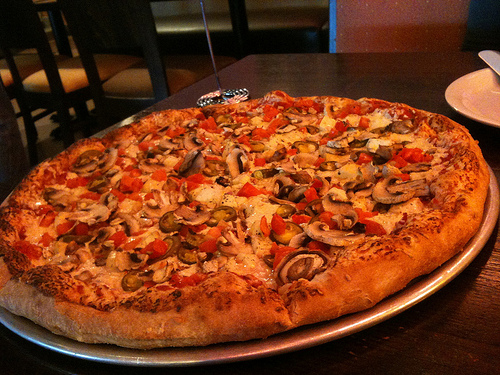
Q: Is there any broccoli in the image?
A: No, there is no broccoli.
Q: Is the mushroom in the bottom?
A: Yes, the mushroom is in the bottom of the image.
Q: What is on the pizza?
A: The mushroom is on the pizza.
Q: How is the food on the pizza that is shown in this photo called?
A: The food is a mushroom.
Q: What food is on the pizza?
A: The food is a mushroom.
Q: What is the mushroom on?
A: The mushroom is on the pizza.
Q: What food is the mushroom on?
A: The mushroom is on the pizza.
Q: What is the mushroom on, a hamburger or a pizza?
A: The mushroom is on a pizza.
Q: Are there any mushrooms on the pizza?
A: Yes, there is a mushroom on the pizza.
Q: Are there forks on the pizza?
A: No, there is a mushroom on the pizza.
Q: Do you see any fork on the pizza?
A: No, there is a mushroom on the pizza.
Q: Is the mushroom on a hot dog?
A: No, the mushroom is on a pizza.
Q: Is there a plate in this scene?
A: Yes, there is a plate.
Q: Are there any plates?
A: Yes, there is a plate.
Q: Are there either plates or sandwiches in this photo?
A: Yes, there is a plate.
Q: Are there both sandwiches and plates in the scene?
A: No, there is a plate but no sandwiches.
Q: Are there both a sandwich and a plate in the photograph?
A: No, there is a plate but no sandwiches.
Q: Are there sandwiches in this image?
A: No, there are no sandwiches.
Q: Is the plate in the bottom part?
A: No, the plate is in the top of the image.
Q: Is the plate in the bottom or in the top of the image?
A: The plate is in the top of the image.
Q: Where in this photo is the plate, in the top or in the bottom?
A: The plate is in the top of the image.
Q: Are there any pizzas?
A: Yes, there is a pizza.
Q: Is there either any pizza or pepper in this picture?
A: Yes, there is a pizza.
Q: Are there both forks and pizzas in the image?
A: No, there is a pizza but no forks.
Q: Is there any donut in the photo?
A: No, there are no donuts.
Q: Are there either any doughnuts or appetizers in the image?
A: No, there are no doughnuts or appetizers.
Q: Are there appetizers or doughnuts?
A: No, there are no doughnuts or appetizers.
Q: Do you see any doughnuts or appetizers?
A: No, there are no doughnuts or appetizers.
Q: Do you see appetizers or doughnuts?
A: No, there are no doughnuts or appetizers.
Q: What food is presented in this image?
A: The food is a pizza.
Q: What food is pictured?
A: The food is a pizza.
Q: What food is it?
A: The food is a pizza.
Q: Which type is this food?
A: That is a pizza.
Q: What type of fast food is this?
A: That is a pizza.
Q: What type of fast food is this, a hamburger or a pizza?
A: That is a pizza.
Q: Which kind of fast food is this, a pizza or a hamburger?
A: That is a pizza.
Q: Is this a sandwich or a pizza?
A: This is a pizza.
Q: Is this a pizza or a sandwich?
A: This is a pizza.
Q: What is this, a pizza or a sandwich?
A: This is a pizza.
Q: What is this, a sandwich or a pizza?
A: This is a pizza.